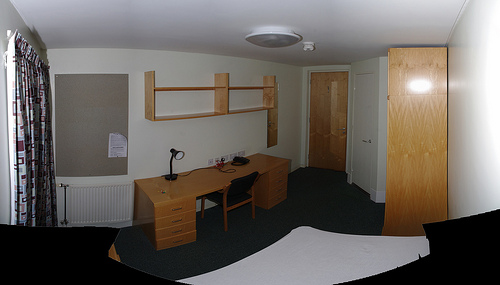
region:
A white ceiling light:
[241, 19, 305, 49]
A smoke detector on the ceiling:
[301, 36, 318, 53]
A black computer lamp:
[162, 145, 188, 182]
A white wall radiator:
[58, 178, 139, 228]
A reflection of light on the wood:
[400, 67, 442, 103]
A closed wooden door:
[303, 66, 359, 178]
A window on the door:
[322, 77, 344, 140]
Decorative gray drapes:
[9, 27, 57, 244]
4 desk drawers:
[151, 193, 201, 253]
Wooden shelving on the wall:
[136, 65, 289, 122]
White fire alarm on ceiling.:
[298, 38, 314, 54]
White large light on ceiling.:
[245, 25, 302, 50]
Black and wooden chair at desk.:
[200, 171, 260, 228]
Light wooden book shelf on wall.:
[145, 62, 280, 119]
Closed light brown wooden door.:
[300, 60, 350, 170]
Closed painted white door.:
[347, 70, 377, 200]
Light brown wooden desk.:
[132, 147, 292, 252]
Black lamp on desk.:
[162, 146, 186, 183]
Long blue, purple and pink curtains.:
[8, 24, 59, 224]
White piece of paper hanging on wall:
[108, 126, 128, 163]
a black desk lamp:
[156, 143, 187, 191]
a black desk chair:
[189, 165, 268, 232]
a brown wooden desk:
[118, 149, 318, 252]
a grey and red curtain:
[5, 20, 67, 252]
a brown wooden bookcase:
[363, 29, 470, 268]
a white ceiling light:
[233, 24, 306, 66]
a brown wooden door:
[286, 55, 371, 189]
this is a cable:
[173, 156, 248, 186]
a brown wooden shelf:
[140, 47, 293, 164]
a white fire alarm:
[296, 38, 321, 56]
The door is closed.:
[294, 63, 357, 179]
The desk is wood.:
[124, 126, 303, 260]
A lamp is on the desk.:
[128, 135, 297, 257]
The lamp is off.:
[160, 135, 210, 199]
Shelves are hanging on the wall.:
[136, 51, 306, 185]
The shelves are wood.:
[136, 56, 294, 143]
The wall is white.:
[132, 38, 318, 234]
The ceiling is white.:
[6, 0, 473, 72]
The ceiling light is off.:
[4, 1, 490, 71]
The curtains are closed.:
[0, 2, 85, 229]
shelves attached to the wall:
[144, 69, 279, 120]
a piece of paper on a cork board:
[105, 130, 125, 157]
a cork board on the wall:
[52, 70, 127, 176]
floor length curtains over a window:
[7, 32, 59, 227]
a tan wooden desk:
[133, 150, 289, 252]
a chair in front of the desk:
[200, 174, 262, 229]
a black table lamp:
[164, 148, 186, 183]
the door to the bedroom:
[307, 68, 345, 166]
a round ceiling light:
[243, 30, 302, 48]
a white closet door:
[351, 71, 375, 193]